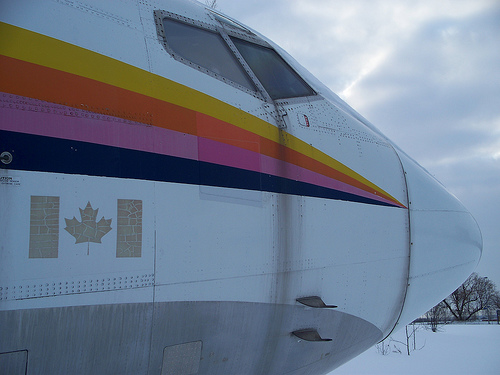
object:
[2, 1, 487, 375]
plane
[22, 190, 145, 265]
flag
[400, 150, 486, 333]
nose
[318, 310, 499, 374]
snow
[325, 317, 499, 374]
ground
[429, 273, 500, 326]
tree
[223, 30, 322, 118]
window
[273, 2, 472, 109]
clouds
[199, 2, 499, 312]
sky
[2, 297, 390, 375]
bottom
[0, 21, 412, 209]
stripe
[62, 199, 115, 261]
leaf